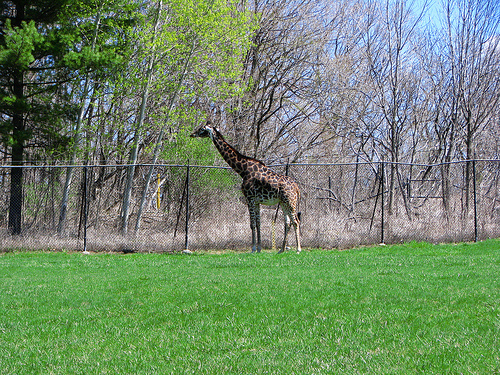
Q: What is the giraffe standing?
A: Grass.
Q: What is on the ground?
A: Green grass.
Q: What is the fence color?
A: Gray.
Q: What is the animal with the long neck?
A: Giraffe.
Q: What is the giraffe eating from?
A: Trees.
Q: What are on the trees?
A: Green leaves.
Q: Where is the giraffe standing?
A: In a field.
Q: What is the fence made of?
A: Metal.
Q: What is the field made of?
A: Green grass.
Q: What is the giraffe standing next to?
A: Fence.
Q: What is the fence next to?
A: Giraffe.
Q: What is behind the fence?
A: Trees.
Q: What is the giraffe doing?
A: Standing.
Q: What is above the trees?
A: Sky.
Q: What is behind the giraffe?
A: A fence line.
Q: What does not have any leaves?
A: The trees.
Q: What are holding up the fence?
A: Black fenceposts.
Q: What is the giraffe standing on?
A: Grass.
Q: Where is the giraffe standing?
A: Next to a fence.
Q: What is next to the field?
A: Chain link fence.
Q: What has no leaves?
A: The trees.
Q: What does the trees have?
A: Green leaves.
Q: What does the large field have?
A: Grass.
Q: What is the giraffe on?
A: Grass.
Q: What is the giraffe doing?
A: Eating leaves.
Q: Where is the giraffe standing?
A: On the grass.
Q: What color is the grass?
A: Green.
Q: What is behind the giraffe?
A: A fence.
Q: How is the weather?
A: Sunny.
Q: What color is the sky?
A: Blue.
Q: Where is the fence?
A: Behind the giraffe.